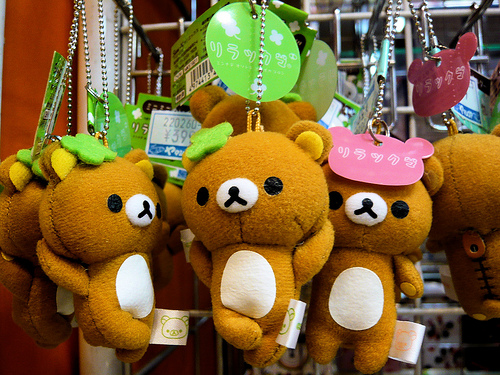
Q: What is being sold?
A: Little teddy bears.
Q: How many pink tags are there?
A: One.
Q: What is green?
A: Tags.